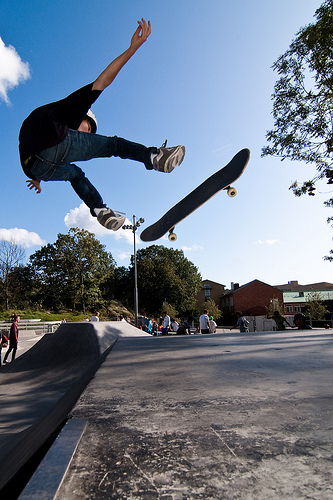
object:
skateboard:
[141, 147, 251, 243]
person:
[157, 314, 165, 335]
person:
[3, 312, 20, 365]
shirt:
[10, 322, 20, 342]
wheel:
[167, 232, 179, 243]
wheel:
[228, 188, 237, 198]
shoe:
[153, 141, 187, 174]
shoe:
[97, 208, 126, 231]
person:
[198, 310, 211, 334]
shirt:
[200, 315, 210, 331]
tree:
[26, 227, 116, 311]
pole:
[133, 213, 141, 328]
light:
[138, 217, 148, 224]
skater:
[19, 19, 186, 231]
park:
[0, 314, 332, 500]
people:
[136, 310, 221, 337]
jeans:
[22, 130, 159, 218]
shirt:
[17, 82, 101, 159]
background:
[2, 225, 332, 343]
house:
[197, 280, 245, 331]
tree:
[128, 244, 200, 317]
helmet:
[86, 110, 100, 133]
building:
[280, 280, 330, 327]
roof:
[282, 290, 333, 304]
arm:
[80, 17, 154, 116]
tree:
[260, 1, 333, 225]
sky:
[0, 0, 332, 286]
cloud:
[0, 38, 32, 102]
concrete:
[55, 331, 331, 500]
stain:
[55, 397, 327, 499]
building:
[231, 277, 276, 324]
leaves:
[32, 227, 113, 316]